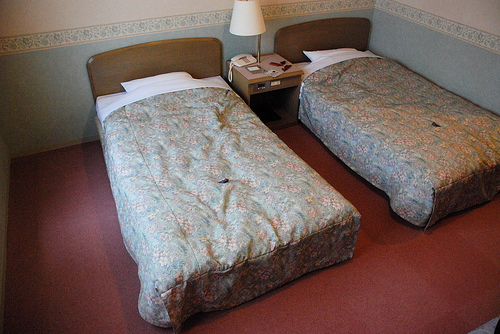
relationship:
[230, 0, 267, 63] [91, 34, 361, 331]
lamp on bed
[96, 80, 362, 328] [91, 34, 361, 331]
blanket on bed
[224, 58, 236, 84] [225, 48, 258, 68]
cord on phone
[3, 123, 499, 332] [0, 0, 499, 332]
maroon carpet in bedroom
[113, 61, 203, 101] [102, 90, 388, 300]
pillow on bed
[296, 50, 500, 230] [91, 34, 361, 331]
bed spread on bed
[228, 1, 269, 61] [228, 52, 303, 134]
lamp on table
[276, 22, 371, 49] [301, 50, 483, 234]
board on bed